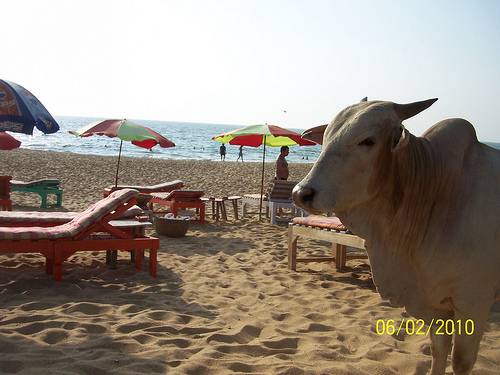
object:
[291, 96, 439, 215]
head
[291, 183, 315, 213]
nose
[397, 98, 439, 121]
horn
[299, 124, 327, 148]
horn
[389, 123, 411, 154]
ear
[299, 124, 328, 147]
ear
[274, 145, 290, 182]
man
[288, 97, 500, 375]
cow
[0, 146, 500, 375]
sand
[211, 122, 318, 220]
umbrella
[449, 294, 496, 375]
leg